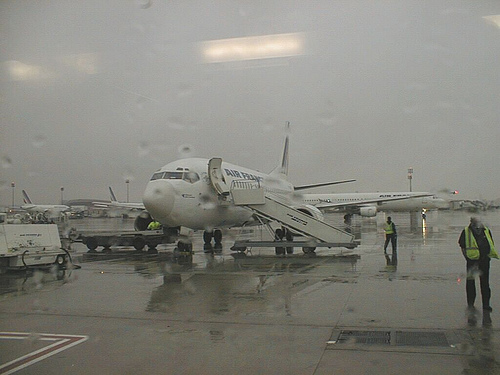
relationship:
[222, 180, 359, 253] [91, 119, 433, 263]
steps leading up to plane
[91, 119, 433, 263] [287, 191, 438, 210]
plane has wing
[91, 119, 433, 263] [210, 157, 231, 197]
plane has door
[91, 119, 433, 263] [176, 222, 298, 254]
plane has landing gear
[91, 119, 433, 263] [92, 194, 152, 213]
plane has wing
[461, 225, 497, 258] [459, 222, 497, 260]
vest for safety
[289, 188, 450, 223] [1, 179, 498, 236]
airplane in background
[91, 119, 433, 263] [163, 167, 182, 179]
plane has window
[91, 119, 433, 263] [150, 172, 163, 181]
plane has window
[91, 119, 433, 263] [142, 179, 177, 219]
plane has nose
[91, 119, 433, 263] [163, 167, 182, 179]
plane has windshield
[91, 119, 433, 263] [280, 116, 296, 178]
plane has tail]\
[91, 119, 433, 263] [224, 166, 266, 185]
plane has writing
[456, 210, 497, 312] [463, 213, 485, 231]
person has head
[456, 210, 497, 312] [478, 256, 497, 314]
person has leg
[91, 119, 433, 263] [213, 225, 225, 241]
plane has wheel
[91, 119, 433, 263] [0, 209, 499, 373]
plane on tarmac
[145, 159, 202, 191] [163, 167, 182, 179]
cockpit has windows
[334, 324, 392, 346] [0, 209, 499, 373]
vent on tarmac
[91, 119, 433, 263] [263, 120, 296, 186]
plane has tail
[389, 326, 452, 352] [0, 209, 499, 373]
drain on tarmac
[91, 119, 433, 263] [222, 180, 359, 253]
plane has stairs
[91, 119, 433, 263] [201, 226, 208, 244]
plane has tire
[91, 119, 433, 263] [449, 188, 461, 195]
plane has light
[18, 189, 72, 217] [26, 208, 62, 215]
jet for passengers